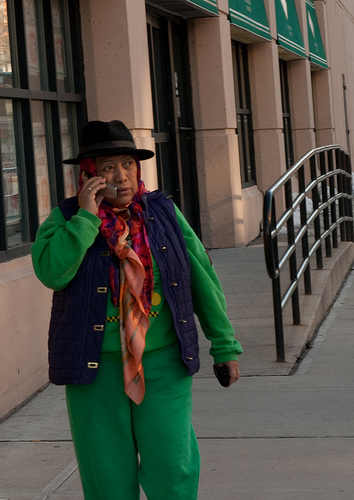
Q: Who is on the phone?
A: A woman.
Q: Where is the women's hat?
A: On her head.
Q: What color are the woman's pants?
A: Green.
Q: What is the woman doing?
A: Talking on the phone.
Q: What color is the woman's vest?
A: Blue.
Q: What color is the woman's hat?
A: Black.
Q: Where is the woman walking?
A: On the sidewalk.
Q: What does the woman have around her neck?
A: Scarves.